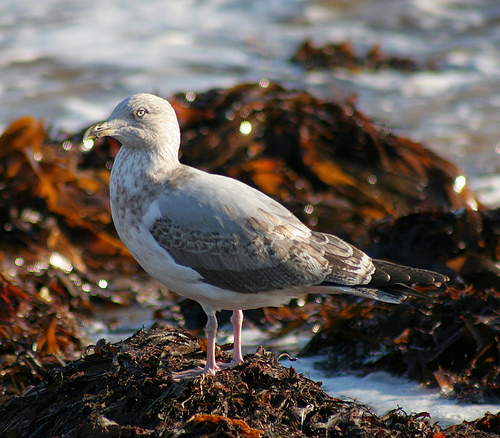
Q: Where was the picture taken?
A: It was taken at the river.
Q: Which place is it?
A: It is a river.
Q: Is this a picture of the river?
A: Yes, it is showing the river.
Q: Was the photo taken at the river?
A: Yes, it was taken in the river.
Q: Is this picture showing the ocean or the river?
A: It is showing the river.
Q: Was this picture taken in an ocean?
A: No, the picture was taken in a river.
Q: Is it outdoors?
A: Yes, it is outdoors.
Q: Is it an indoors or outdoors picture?
A: It is outdoors.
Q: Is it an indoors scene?
A: No, it is outdoors.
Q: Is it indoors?
A: No, it is outdoors.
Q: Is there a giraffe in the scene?
A: No, there are no giraffes.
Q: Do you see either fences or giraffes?
A: No, there are no giraffes or fences.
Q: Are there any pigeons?
A: Yes, there is a pigeon.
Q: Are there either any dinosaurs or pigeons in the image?
A: Yes, there is a pigeon.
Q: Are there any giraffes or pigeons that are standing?
A: Yes, the pigeon is standing.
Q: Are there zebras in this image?
A: No, there are no zebras.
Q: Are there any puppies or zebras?
A: No, there are no zebras or puppies.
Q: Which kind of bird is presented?
A: The bird is a pigeon.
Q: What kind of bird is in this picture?
A: The bird is a pigeon.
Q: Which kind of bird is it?
A: The bird is a pigeon.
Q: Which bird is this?
A: That is a pigeon.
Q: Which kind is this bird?
A: That is a pigeon.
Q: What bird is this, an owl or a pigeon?
A: That is a pigeon.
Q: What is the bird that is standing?
A: The bird is a pigeon.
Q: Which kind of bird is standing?
A: The bird is a pigeon.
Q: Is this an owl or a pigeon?
A: This is a pigeon.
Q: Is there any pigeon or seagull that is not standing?
A: No, there is a pigeon but it is standing.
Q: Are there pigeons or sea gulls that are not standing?
A: No, there is a pigeon but it is standing.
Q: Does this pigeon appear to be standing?
A: Yes, the pigeon is standing.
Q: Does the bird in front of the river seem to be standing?
A: Yes, the pigeon is standing.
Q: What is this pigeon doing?
A: The pigeon is standing.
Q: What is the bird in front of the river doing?
A: The pigeon is standing.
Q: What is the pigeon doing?
A: The pigeon is standing.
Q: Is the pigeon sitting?
A: No, the pigeon is standing.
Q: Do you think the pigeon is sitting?
A: No, the pigeon is standing.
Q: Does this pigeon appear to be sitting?
A: No, the pigeon is standing.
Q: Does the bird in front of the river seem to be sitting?
A: No, the pigeon is standing.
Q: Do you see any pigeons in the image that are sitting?
A: No, there is a pigeon but it is standing.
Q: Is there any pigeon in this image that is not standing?
A: No, there is a pigeon but it is standing.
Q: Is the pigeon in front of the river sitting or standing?
A: The pigeon is standing.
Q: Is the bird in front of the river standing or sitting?
A: The pigeon is standing.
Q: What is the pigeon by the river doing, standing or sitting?
A: The pigeon is standing.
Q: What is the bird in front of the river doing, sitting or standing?
A: The pigeon is standing.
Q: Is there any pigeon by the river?
A: Yes, there is a pigeon by the river.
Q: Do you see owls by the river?
A: No, there is a pigeon by the river.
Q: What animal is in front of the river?
A: The pigeon is in front of the river.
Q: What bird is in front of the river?
A: The bird is a pigeon.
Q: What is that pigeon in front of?
A: The pigeon is in front of the river.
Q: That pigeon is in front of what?
A: The pigeon is in front of the river.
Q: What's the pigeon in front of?
A: The pigeon is in front of the river.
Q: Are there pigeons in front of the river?
A: Yes, there is a pigeon in front of the river.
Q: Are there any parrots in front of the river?
A: No, there is a pigeon in front of the river.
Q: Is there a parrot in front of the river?
A: No, there is a pigeon in front of the river.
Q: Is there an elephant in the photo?
A: No, there are no elephants.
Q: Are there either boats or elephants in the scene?
A: No, there are no elephants or boats.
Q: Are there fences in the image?
A: No, there are no fences.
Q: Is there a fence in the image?
A: No, there are no fences.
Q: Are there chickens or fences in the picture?
A: No, there are no fences or chickens.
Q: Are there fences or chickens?
A: No, there are no fences or chickens.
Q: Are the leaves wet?
A: Yes, the leaves are wet.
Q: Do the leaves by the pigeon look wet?
A: Yes, the leaves are wet.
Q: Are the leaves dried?
A: No, the leaves are wet.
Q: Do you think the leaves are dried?
A: No, the leaves are wet.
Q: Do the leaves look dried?
A: No, the leaves are wet.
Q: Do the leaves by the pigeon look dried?
A: No, the leaves are wet.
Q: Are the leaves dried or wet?
A: The leaves are wet.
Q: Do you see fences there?
A: No, there are no fences.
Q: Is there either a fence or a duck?
A: No, there are no fences or ducks.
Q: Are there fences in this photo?
A: No, there are no fences.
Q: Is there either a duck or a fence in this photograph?
A: No, there are no fences or ducks.